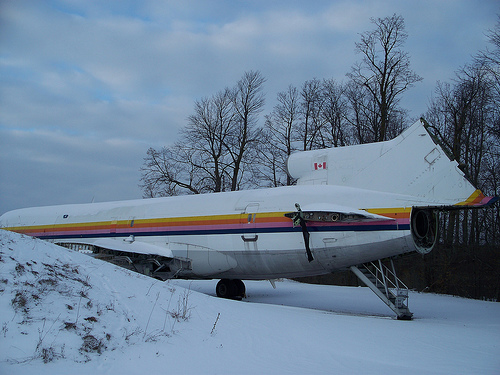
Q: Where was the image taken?
A: It was taken at the forest.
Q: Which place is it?
A: It is a forest.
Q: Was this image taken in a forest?
A: Yes, it was taken in a forest.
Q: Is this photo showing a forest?
A: Yes, it is showing a forest.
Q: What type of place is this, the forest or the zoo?
A: It is the forest.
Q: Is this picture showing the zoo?
A: No, the picture is showing the forest.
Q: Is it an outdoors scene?
A: Yes, it is outdoors.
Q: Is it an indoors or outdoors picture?
A: It is outdoors.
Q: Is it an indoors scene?
A: No, it is outdoors.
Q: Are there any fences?
A: No, there are no fences.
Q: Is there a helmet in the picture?
A: No, there are no helmets.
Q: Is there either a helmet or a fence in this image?
A: No, there are no helmets or fences.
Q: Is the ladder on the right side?
A: Yes, the ladder is on the right of the image.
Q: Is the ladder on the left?
A: No, the ladder is on the right of the image.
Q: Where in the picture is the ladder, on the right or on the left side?
A: The ladder is on the right of the image.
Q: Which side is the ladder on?
A: The ladder is on the right of the image.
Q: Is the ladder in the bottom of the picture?
A: Yes, the ladder is in the bottom of the image.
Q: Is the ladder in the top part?
A: No, the ladder is in the bottom of the image.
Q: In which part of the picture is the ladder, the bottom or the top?
A: The ladder is in the bottom of the image.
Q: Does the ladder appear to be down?
A: Yes, the ladder is down.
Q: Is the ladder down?
A: Yes, the ladder is down.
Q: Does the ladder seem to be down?
A: Yes, the ladder is down.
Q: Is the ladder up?
A: No, the ladder is down.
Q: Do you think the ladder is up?
A: No, the ladder is down.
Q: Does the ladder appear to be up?
A: No, the ladder is down.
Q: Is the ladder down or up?
A: The ladder is down.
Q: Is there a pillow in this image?
A: No, there are no pillows.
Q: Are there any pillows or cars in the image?
A: No, there are no pillows or cars.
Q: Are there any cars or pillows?
A: No, there are no pillows or cars.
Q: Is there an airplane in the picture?
A: Yes, there is an airplane.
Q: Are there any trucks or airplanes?
A: Yes, there is an airplane.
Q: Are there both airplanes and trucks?
A: No, there is an airplane but no trucks.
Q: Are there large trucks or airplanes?
A: Yes, there is a large airplane.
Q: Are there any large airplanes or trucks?
A: Yes, there is a large airplane.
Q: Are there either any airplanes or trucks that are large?
A: Yes, the airplane is large.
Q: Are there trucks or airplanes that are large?
A: Yes, the airplane is large.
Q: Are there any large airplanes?
A: Yes, there is a large airplane.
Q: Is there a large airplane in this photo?
A: Yes, there is a large airplane.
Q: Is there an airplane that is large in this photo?
A: Yes, there is a large airplane.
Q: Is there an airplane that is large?
A: Yes, there is an airplane that is large.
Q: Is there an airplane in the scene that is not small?
A: Yes, there is a large airplane.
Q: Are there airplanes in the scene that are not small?
A: Yes, there is a large airplane.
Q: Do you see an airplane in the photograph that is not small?
A: Yes, there is a large airplane.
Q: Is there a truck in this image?
A: No, there are no trucks.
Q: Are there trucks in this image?
A: No, there are no trucks.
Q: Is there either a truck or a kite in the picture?
A: No, there are no trucks or kites.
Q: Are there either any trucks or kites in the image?
A: No, there are no trucks or kites.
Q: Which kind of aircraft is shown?
A: The aircraft is an airplane.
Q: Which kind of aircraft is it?
A: The aircraft is an airplane.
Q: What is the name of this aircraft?
A: This is an airplane.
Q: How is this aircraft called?
A: This is an airplane.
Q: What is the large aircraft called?
A: The aircraft is an airplane.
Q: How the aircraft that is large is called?
A: The aircraft is an airplane.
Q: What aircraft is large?
A: The aircraft is an airplane.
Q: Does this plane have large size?
A: Yes, the plane is large.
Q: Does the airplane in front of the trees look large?
A: Yes, the plane is large.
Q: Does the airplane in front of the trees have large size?
A: Yes, the plane is large.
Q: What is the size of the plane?
A: The plane is large.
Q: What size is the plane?
A: The plane is large.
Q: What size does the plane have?
A: The plane has large size.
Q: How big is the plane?
A: The plane is large.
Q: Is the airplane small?
A: No, the airplane is large.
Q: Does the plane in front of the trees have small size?
A: No, the airplane is large.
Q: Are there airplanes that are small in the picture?
A: No, there is an airplane but it is large.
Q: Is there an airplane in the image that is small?
A: No, there is an airplane but it is large.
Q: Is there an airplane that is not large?
A: No, there is an airplane but it is large.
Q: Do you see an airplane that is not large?
A: No, there is an airplane but it is large.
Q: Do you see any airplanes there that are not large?
A: No, there is an airplane but it is large.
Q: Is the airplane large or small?
A: The airplane is large.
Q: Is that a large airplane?
A: Yes, that is a large airplane.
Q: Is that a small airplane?
A: No, that is a large airplane.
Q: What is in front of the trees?
A: The airplane is in front of the trees.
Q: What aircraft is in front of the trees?
A: The aircraft is an airplane.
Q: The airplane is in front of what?
A: The airplane is in front of the trees.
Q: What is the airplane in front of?
A: The airplane is in front of the trees.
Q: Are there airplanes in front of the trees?
A: Yes, there is an airplane in front of the trees.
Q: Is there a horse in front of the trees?
A: No, there is an airplane in front of the trees.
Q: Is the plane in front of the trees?
A: Yes, the plane is in front of the trees.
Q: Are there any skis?
A: No, there are no skis.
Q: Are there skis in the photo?
A: No, there are no skis.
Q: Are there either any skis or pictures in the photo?
A: No, there are no skis or pictures.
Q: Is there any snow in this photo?
A: Yes, there is snow.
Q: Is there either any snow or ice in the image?
A: Yes, there is snow.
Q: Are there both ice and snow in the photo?
A: No, there is snow but no ice.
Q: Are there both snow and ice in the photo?
A: No, there is snow but no ice.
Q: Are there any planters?
A: No, there are no planters.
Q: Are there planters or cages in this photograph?
A: No, there are no planters or cages.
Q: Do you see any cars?
A: No, there are no cars.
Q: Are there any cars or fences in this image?
A: No, there are no cars or fences.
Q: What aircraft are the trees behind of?
A: The trees are behind the airplane.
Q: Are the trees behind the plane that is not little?
A: Yes, the trees are behind the airplane.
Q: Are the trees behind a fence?
A: No, the trees are behind the airplane.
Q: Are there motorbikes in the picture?
A: No, there are no motorbikes.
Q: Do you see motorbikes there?
A: No, there are no motorbikes.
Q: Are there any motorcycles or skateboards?
A: No, there are no motorcycles or skateboards.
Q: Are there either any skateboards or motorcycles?
A: No, there are no motorcycles or skateboards.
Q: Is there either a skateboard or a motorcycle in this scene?
A: No, there are no motorcycles or skateboards.